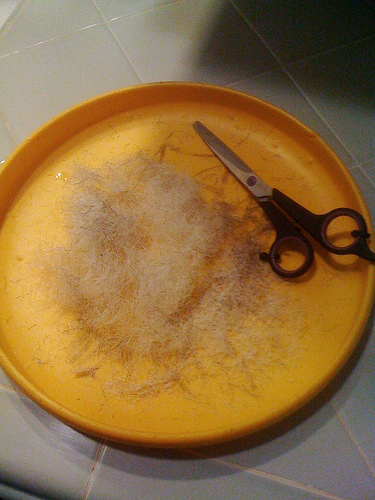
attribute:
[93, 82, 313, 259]
plate — yellow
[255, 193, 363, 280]
handle — black 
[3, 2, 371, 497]
floor — tiled, white 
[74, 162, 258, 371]
hair — white 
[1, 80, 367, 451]
plate — orange , yellow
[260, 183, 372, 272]
handle — black 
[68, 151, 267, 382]
hairs — white and grey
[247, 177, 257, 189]
screw — dark 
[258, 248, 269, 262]
notch — black 